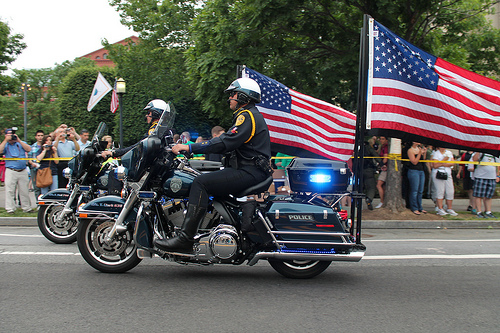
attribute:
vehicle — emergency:
[243, 144, 345, 263]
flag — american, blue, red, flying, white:
[352, 22, 484, 175]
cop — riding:
[216, 70, 277, 120]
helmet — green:
[183, 70, 270, 108]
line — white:
[390, 246, 467, 274]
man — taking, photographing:
[3, 88, 97, 156]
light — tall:
[9, 71, 46, 147]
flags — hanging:
[83, 71, 141, 122]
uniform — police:
[195, 108, 281, 200]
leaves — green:
[217, 20, 276, 49]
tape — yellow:
[369, 148, 440, 181]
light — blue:
[283, 171, 367, 217]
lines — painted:
[11, 228, 72, 277]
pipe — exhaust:
[280, 227, 381, 270]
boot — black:
[155, 195, 213, 284]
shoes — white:
[398, 191, 454, 224]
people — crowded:
[8, 121, 114, 193]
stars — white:
[389, 44, 416, 80]